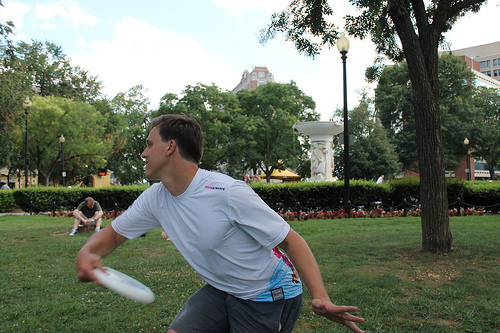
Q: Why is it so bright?
A: Sunny.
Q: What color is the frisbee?
A: White.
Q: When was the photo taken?
A: Day time.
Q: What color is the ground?
A: Green.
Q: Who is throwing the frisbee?
A: The man.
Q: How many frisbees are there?
A: One.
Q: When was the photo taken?
A: Daytime.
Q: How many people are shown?
A: Two.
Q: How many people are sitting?
A: 1.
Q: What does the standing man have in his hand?
A: Frisbee.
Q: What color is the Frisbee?
A: White.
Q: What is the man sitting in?
A: Grass.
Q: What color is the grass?
A: Green.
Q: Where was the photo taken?
A: In a park.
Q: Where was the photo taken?
A: In a park.